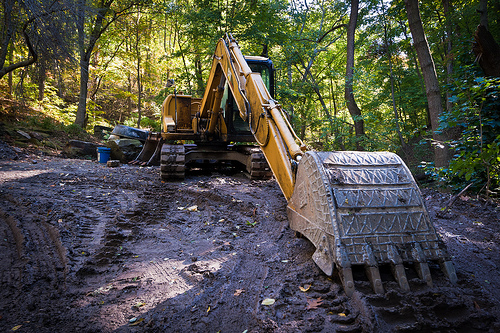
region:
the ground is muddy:
[129, 196, 280, 327]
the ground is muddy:
[174, 194, 333, 316]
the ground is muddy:
[171, 157, 241, 304]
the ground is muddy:
[144, 260, 241, 331]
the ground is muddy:
[156, 243, 218, 324]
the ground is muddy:
[188, 259, 242, 319]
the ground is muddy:
[174, 228, 254, 315]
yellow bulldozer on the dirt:
[137, 28, 472, 305]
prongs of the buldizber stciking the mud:
[331, 250, 468, 300]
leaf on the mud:
[260, 290, 276, 307]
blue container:
[91, 138, 110, 163]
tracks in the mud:
[63, 196, 117, 259]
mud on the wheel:
[158, 146, 183, 176]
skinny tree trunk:
[393, 5, 463, 165]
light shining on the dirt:
[146, 261, 183, 291]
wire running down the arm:
[226, 48, 275, 155]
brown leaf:
[303, 295, 326, 312]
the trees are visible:
[111, 76, 434, 127]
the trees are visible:
[189, 100, 467, 167]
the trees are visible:
[139, 8, 361, 85]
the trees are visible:
[161, 11, 490, 150]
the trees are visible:
[76, 5, 214, 84]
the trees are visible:
[297, 0, 432, 50]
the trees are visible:
[304, 73, 404, 113]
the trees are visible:
[287, 3, 407, 105]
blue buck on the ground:
[90, 140, 117, 170]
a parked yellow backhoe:
[150, 26, 468, 301]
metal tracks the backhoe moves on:
[153, 136, 273, 177]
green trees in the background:
[275, 6, 498, 186]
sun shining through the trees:
[89, 18, 204, 91]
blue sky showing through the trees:
[291, 3, 414, 53]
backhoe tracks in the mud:
[90, 180, 185, 293]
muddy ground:
[26, 180, 215, 332]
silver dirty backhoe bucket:
[286, 147, 469, 303]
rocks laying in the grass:
[12, 122, 60, 144]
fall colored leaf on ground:
[303, 294, 321, 311]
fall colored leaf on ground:
[255, 295, 272, 307]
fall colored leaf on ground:
[219, 238, 230, 247]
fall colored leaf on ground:
[202, 303, 218, 316]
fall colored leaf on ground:
[458, 190, 475, 205]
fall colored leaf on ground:
[181, 197, 198, 209]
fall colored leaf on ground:
[185, 202, 198, 211]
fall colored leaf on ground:
[232, 284, 253, 296]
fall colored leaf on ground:
[58, 176, 72, 183]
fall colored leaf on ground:
[293, 277, 309, 293]